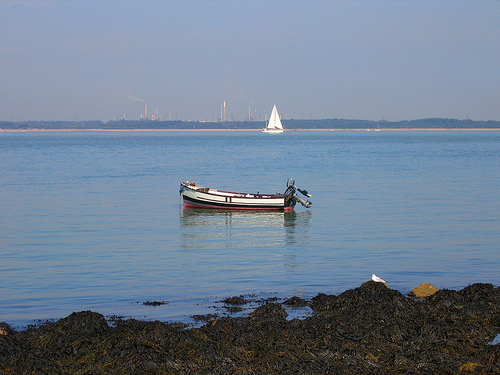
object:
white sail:
[262, 104, 284, 134]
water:
[0, 129, 499, 317]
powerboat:
[179, 177, 312, 213]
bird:
[369, 273, 386, 284]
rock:
[358, 296, 396, 321]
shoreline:
[0, 276, 499, 374]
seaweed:
[2, 287, 499, 374]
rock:
[407, 282, 437, 299]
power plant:
[137, 98, 175, 121]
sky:
[0, 0, 499, 123]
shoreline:
[0, 123, 499, 137]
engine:
[283, 177, 311, 209]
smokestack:
[142, 99, 149, 120]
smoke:
[127, 94, 146, 103]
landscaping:
[0, 117, 499, 128]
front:
[180, 178, 201, 208]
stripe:
[183, 196, 286, 209]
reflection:
[180, 208, 311, 241]